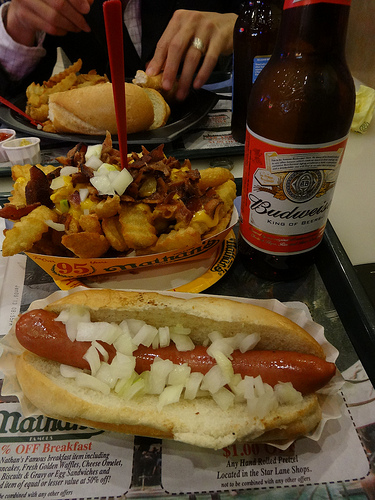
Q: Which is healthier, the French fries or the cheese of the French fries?
A: The cheese is healthier than the French fries.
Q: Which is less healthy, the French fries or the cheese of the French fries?
A: The French fries is less healthy than the cheese.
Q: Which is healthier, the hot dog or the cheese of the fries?
A: The cheese is healthier than the hot dog.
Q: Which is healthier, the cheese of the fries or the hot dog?
A: The cheese is healthier than the hot dog.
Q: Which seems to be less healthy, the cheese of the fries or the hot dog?
A: The hot dog is less healthy than the cheese.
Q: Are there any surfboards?
A: No, there are no surfboards.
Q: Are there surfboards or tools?
A: No, there are no surfboards or tools.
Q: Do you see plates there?
A: Yes, there is a plate.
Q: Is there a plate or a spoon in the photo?
A: Yes, there is a plate.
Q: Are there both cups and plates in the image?
A: Yes, there are both a plate and a cup.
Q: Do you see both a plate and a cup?
A: Yes, there are both a plate and a cup.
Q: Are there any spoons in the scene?
A: No, there are no spoons.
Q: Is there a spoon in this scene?
A: No, there are no spoons.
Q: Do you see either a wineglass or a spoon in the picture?
A: No, there are no spoons or wine glasses.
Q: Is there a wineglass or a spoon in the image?
A: No, there are no spoons or wine glasses.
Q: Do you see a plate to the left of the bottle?
A: Yes, there is a plate to the left of the bottle.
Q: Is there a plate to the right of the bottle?
A: No, the plate is to the left of the bottle.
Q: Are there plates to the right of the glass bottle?
A: No, the plate is to the left of the bottle.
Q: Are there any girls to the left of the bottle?
A: No, there is a plate to the left of the bottle.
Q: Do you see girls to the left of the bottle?
A: No, there is a plate to the left of the bottle.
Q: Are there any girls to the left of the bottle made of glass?
A: No, there is a plate to the left of the bottle.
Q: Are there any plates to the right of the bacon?
A: Yes, there is a plate to the right of the bacon.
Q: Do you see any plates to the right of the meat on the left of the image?
A: Yes, there is a plate to the right of the bacon.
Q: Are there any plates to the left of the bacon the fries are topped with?
A: No, the plate is to the right of the bacon.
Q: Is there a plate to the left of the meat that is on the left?
A: No, the plate is to the right of the bacon.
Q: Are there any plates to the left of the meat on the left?
A: No, the plate is to the right of the bacon.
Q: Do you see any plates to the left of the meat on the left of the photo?
A: No, the plate is to the right of the bacon.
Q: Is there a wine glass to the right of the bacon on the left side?
A: No, there is a plate to the right of the bacon.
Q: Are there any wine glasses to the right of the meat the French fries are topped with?
A: No, there is a plate to the right of the bacon.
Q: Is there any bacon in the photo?
A: Yes, there is bacon.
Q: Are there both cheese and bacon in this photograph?
A: Yes, there are both bacon and cheese.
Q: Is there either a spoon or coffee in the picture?
A: No, there are no coffee or spoons.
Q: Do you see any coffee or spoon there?
A: No, there are no coffee or spoons.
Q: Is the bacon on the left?
A: Yes, the bacon is on the left of the image.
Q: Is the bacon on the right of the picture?
A: No, the bacon is on the left of the image.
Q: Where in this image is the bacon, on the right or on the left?
A: The bacon is on the left of the image.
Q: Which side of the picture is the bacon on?
A: The bacon is on the left of the image.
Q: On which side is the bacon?
A: The bacon is on the left of the image.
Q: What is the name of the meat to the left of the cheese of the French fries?
A: The meat is bacon.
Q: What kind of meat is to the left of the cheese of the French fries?
A: The meat is bacon.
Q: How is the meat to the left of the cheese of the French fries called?
A: The meat is bacon.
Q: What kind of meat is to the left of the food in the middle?
A: The meat is bacon.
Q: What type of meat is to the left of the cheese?
A: The meat is bacon.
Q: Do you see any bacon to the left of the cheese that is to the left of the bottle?
A: Yes, there is bacon to the left of the cheese.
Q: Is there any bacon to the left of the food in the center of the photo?
A: Yes, there is bacon to the left of the cheese.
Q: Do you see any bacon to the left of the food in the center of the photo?
A: Yes, there is bacon to the left of the cheese.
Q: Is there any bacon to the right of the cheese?
A: No, the bacon is to the left of the cheese.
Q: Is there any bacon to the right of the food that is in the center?
A: No, the bacon is to the left of the cheese.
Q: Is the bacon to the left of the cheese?
A: Yes, the bacon is to the left of the cheese.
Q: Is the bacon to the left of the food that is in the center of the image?
A: Yes, the bacon is to the left of the cheese.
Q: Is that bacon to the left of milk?
A: No, the bacon is to the left of the cheese.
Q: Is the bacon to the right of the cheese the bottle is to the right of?
A: No, the bacon is to the left of the cheese.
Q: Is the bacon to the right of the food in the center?
A: No, the bacon is to the left of the cheese.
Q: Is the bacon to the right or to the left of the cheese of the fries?
A: The bacon is to the left of the cheese.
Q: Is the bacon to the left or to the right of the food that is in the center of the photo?
A: The bacon is to the left of the cheese.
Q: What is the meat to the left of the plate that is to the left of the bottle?
A: The meat is bacon.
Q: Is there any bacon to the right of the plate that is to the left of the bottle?
A: No, the bacon is to the left of the plate.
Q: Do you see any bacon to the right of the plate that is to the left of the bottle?
A: No, the bacon is to the left of the plate.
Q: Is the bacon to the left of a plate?
A: Yes, the bacon is to the left of a plate.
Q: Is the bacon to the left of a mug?
A: No, the bacon is to the left of a plate.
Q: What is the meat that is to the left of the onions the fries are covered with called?
A: The meat is bacon.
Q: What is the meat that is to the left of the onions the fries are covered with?
A: The meat is bacon.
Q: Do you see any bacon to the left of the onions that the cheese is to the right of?
A: Yes, there is bacon to the left of the onions.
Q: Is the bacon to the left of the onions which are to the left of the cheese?
A: Yes, the bacon is to the left of the onions.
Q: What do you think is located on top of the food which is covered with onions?
A: The bacon is on top of the fries.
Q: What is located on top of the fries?
A: The bacon is on top of the fries.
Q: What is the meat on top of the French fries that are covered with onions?
A: The meat is bacon.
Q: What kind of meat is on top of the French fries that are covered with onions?
A: The meat is bacon.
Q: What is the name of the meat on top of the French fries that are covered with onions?
A: The meat is bacon.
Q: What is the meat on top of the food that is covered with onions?
A: The meat is bacon.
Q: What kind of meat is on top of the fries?
A: The meat is bacon.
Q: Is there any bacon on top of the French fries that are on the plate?
A: Yes, there is bacon on top of the French fries.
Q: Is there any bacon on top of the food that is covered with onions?
A: Yes, there is bacon on top of the French fries.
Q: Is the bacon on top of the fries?
A: Yes, the bacon is on top of the fries.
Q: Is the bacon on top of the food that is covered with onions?
A: Yes, the bacon is on top of the fries.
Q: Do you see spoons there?
A: No, there are no spoons.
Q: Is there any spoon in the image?
A: No, there are no spoons.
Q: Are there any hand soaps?
A: No, there are no hand soaps.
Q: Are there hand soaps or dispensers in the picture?
A: No, there are no hand soaps or dispensers.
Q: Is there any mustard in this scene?
A: Yes, there is mustard.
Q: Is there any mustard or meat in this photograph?
A: Yes, there is mustard.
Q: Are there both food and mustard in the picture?
A: Yes, there are both mustard and food.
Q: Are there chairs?
A: No, there are no chairs.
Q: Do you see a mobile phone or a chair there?
A: No, there are no chairs or cell phones.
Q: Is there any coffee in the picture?
A: No, there is no coffee.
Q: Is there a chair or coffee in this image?
A: No, there are no coffee or chairs.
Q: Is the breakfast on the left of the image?
A: Yes, the breakfast is on the left of the image.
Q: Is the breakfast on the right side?
A: No, the breakfast is on the left of the image.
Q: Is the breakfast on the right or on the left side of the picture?
A: The breakfast is on the left of the image.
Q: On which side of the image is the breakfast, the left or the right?
A: The breakfast is on the left of the image.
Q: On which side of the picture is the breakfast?
A: The breakfast is on the left of the image.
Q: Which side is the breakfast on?
A: The breakfast is on the left of the image.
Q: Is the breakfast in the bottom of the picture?
A: Yes, the breakfast is in the bottom of the image.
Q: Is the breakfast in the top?
A: No, the breakfast is in the bottom of the image.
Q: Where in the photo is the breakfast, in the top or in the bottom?
A: The breakfast is in the bottom of the image.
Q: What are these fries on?
A: The fries are on the plate.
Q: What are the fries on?
A: The fries are on the plate.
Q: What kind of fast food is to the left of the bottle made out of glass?
A: The food is fries.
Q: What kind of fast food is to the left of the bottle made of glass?
A: The food is fries.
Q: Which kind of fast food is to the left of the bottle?
A: The food is fries.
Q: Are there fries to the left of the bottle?
A: Yes, there are fries to the left of the bottle.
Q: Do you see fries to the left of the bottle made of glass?
A: Yes, there are fries to the left of the bottle.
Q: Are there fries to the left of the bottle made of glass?
A: Yes, there are fries to the left of the bottle.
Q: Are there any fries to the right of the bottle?
A: No, the fries are to the left of the bottle.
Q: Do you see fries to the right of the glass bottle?
A: No, the fries are to the left of the bottle.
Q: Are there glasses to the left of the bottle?
A: No, there are fries to the left of the bottle.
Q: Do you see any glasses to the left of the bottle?
A: No, there are fries to the left of the bottle.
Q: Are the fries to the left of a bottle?
A: Yes, the fries are to the left of a bottle.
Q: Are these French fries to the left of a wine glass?
A: No, the French fries are to the left of a bottle.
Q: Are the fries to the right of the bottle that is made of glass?
A: No, the fries are to the left of the bottle.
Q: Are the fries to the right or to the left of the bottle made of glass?
A: The fries are to the left of the bottle.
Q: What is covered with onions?
A: The French fries are covered with onions.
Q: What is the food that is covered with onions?
A: The food is fries.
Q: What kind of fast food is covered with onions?
A: The food is fries.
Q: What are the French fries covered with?
A: The French fries are covered with onions.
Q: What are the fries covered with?
A: The French fries are covered with onions.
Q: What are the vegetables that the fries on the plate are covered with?
A: The vegetables are onions.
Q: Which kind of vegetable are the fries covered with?
A: The French fries are covered with onions.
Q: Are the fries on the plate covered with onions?
A: Yes, the fries are covered with onions.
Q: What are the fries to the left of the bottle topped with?
A: The fries are topped with bacon.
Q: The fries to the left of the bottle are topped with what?
A: The fries are topped with bacon.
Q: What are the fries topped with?
A: The fries are topped with bacon.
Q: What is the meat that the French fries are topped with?
A: The meat is bacon.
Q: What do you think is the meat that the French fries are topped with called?
A: The meat is bacon.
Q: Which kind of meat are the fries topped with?
A: The French fries are topped with bacon.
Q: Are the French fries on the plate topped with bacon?
A: Yes, the French fries are topped with bacon.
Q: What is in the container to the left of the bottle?
A: The fries are in the container.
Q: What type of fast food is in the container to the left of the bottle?
A: The food is fries.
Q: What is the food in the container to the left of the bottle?
A: The food is fries.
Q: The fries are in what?
A: The fries are in the container.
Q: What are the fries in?
A: The fries are in the container.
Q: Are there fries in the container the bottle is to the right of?
A: Yes, there are fries in the container.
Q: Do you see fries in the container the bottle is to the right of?
A: Yes, there are fries in the container.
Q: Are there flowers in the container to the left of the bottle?
A: No, there are fries in the container.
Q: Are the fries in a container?
A: Yes, the fries are in a container.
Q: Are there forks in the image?
A: Yes, there is a fork.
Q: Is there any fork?
A: Yes, there is a fork.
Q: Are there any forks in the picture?
A: Yes, there is a fork.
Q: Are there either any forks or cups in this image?
A: Yes, there is a fork.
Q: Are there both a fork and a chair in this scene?
A: No, there is a fork but no chairs.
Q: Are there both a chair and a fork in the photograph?
A: No, there is a fork but no chairs.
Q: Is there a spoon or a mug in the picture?
A: No, there are no spoons or mugs.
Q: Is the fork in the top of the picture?
A: Yes, the fork is in the top of the image.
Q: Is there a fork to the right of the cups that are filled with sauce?
A: Yes, there is a fork to the right of the cups.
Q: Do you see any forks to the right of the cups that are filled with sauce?
A: Yes, there is a fork to the right of the cups.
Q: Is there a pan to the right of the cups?
A: No, there is a fork to the right of the cups.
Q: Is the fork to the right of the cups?
A: Yes, the fork is to the right of the cups.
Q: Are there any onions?
A: Yes, there are onions.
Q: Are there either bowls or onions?
A: Yes, there are onions.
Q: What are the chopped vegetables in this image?
A: The vegetables are onions.